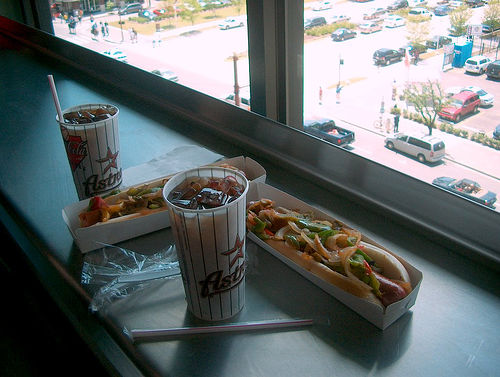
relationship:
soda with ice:
[61, 105, 110, 127] [76, 105, 107, 121]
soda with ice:
[160, 165, 248, 220] [194, 186, 229, 204]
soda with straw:
[61, 105, 110, 127] [44, 70, 72, 131]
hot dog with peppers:
[247, 189, 420, 317] [298, 218, 337, 245]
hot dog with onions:
[247, 189, 420, 317] [307, 236, 360, 265]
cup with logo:
[58, 103, 134, 205] [81, 162, 125, 192]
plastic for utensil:
[76, 240, 192, 317] [116, 265, 181, 288]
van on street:
[381, 124, 455, 168] [311, 97, 496, 207]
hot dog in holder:
[247, 189, 420, 317] [242, 176, 424, 328]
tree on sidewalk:
[415, 73, 445, 137] [314, 82, 499, 175]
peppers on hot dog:
[298, 218, 337, 245] [247, 189, 420, 317]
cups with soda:
[58, 104, 248, 327] [68, 104, 242, 212]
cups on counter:
[58, 104, 248, 327] [1, 44, 499, 370]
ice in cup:
[76, 105, 107, 121] [58, 103, 134, 205]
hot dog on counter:
[247, 189, 420, 317] [1, 44, 499, 370]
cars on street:
[307, 106, 496, 207] [311, 97, 496, 207]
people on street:
[378, 105, 405, 136] [311, 97, 496, 207]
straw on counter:
[123, 316, 325, 337] [1, 44, 499, 370]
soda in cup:
[160, 165, 248, 220] [163, 161, 261, 324]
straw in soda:
[44, 70, 72, 131] [61, 105, 110, 127]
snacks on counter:
[41, 73, 425, 334] [1, 44, 499, 370]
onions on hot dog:
[307, 236, 360, 265] [247, 189, 420, 317]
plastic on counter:
[76, 240, 192, 317] [1, 44, 499, 370]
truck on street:
[307, 112, 359, 147] [311, 97, 496, 207]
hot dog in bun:
[247, 189, 420, 317] [251, 197, 402, 299]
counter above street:
[1, 44, 499, 370] [311, 97, 496, 207]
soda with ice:
[160, 165, 248, 220] [217, 179, 236, 194]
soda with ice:
[61, 105, 110, 127] [96, 105, 115, 117]